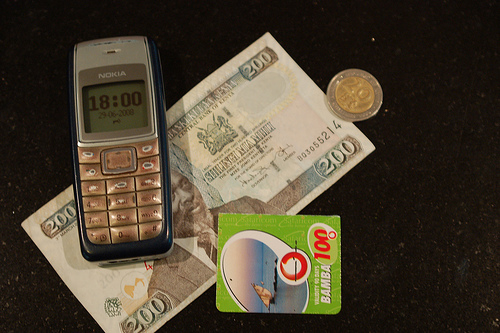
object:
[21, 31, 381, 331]
note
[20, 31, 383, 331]
money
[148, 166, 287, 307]
man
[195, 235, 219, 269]
tie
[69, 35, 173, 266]
phone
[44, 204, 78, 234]
numbers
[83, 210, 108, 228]
buttons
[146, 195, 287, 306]
suit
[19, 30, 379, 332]
bill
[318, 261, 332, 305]
word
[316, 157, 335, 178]
numbers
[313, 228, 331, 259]
100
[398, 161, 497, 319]
surface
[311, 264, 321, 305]
words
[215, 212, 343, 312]
card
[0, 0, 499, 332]
table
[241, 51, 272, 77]
number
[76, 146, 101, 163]
buttons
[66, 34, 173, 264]
cell phone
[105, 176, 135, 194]
button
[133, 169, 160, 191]
button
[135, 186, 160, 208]
button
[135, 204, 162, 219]
button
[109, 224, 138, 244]
button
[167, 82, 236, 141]
words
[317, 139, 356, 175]
200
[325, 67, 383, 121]
coin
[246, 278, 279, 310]
sailboat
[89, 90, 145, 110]
time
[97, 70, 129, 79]
name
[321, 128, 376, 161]
corner